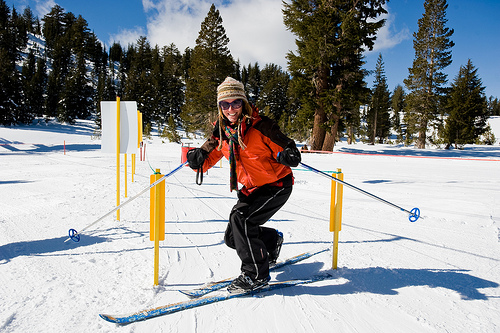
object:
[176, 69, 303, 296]
girl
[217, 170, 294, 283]
pants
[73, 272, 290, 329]
ski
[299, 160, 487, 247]
pole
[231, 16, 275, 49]
clouds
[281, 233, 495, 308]
shadow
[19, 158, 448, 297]
snow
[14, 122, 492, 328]
ground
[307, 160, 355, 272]
yellow post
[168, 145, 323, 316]
lane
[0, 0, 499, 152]
trees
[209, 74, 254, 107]
button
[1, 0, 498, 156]
evergreen trees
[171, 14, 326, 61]
white clouds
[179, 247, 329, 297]
ski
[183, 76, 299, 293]
woman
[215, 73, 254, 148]
hat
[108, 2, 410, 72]
cloud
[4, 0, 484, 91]
sky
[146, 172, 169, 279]
post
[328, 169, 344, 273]
post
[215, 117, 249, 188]
scarf